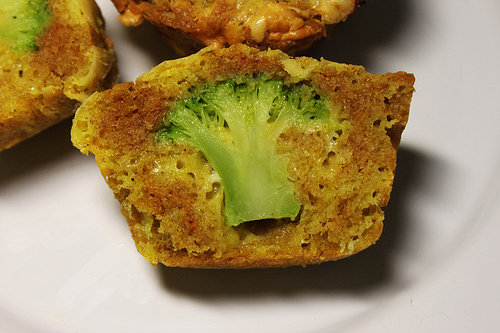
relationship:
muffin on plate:
[81, 65, 401, 269] [2, 174, 252, 326]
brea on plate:
[106, 60, 340, 250] [79, 251, 461, 330]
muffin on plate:
[134, 71, 364, 229] [13, 189, 160, 327]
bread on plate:
[92, 90, 252, 262] [22, 208, 172, 311]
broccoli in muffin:
[156, 76, 332, 229] [87, 65, 287, 242]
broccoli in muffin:
[156, 76, 332, 229] [92, 74, 457, 330]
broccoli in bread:
[156, 76, 332, 229] [84, 74, 242, 236]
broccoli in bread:
[156, 76, 332, 229] [83, 46, 450, 305]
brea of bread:
[71, 46, 417, 267] [75, 41, 440, 295]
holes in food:
[128, 182, 226, 285] [76, 41, 464, 313]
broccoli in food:
[156, 76, 332, 229] [65, 36, 428, 330]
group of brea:
[8, 3, 485, 265] [71, 46, 417, 267]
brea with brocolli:
[71, 46, 417, 267] [159, 70, 379, 264]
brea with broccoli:
[71, 46, 417, 267] [156, 76, 332, 229]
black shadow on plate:
[399, 149, 424, 289] [16, 5, 485, 307]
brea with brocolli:
[71, 46, 417, 267] [151, 62, 356, 241]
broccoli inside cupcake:
[156, 76, 332, 229] [82, 15, 431, 304]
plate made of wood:
[16, 5, 485, 307] [60, 200, 210, 329]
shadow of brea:
[156, 145, 419, 302] [71, 46, 417, 267]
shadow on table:
[156, 145, 419, 302] [422, 44, 484, 331]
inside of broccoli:
[250, 128, 268, 218] [156, 76, 332, 229]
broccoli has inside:
[156, 76, 332, 229] [250, 128, 268, 218]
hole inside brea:
[113, 185, 131, 205] [71, 46, 417, 267]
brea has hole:
[71, 46, 417, 267] [113, 185, 131, 205]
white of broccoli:
[250, 181, 268, 216] [156, 76, 332, 229]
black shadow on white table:
[399, 149, 424, 289] [430, 114, 485, 331]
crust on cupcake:
[205, 8, 290, 39] [109, 0, 357, 47]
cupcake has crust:
[109, 0, 357, 47] [205, 8, 290, 39]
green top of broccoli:
[162, 78, 325, 118] [156, 76, 332, 229]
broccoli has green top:
[156, 76, 332, 229] [162, 78, 325, 118]